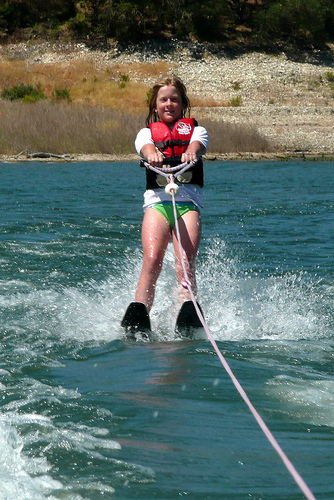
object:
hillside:
[0, 0, 333, 159]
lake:
[0, 154, 333, 499]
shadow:
[106, 337, 199, 452]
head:
[151, 76, 185, 124]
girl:
[133, 75, 209, 317]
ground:
[0, 0, 333, 164]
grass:
[117, 74, 131, 82]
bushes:
[0, 82, 46, 102]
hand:
[146, 151, 163, 166]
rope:
[167, 173, 316, 499]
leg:
[170, 209, 200, 307]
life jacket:
[144, 118, 204, 193]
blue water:
[0, 161, 333, 499]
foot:
[124, 309, 150, 325]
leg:
[133, 206, 172, 315]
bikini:
[149, 201, 197, 234]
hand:
[180, 148, 200, 164]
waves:
[0, 348, 128, 500]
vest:
[144, 117, 204, 192]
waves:
[53, 238, 334, 345]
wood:
[13, 148, 75, 163]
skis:
[173, 298, 203, 337]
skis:
[118, 301, 152, 333]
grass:
[225, 94, 244, 110]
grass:
[228, 79, 242, 94]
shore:
[0, 57, 333, 163]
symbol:
[176, 122, 191, 135]